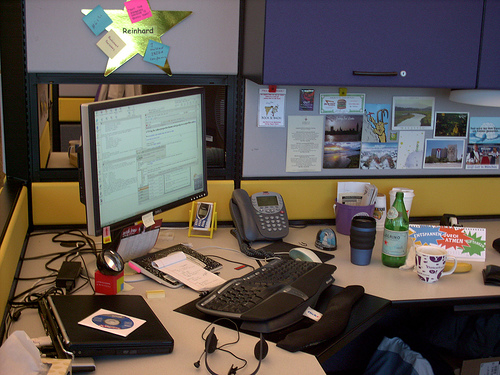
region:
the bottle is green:
[376, 181, 413, 270]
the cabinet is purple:
[266, 3, 491, 95]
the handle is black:
[347, 63, 401, 90]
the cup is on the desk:
[342, 209, 378, 268]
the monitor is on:
[81, 97, 210, 224]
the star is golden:
[64, 0, 209, 77]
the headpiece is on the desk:
[192, 316, 283, 373]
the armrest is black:
[279, 282, 366, 360]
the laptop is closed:
[31, 283, 180, 354]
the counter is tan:
[175, 322, 189, 366]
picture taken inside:
[9, 6, 493, 371]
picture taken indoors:
[26, 6, 478, 373]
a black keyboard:
[180, 251, 350, 341]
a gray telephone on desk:
[227, 185, 287, 240]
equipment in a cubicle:
[17, 105, 487, 367]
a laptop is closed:
[45, 295, 160, 361]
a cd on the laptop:
[77, 310, 142, 340]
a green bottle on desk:
[380, 185, 405, 270]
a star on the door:
[61, 6, 211, 71]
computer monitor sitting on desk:
[75, 85, 211, 242]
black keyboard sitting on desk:
[198, 251, 339, 326]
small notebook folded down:
[28, 285, 180, 367]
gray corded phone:
[226, 186, 294, 261]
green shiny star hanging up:
[80, 3, 198, 80]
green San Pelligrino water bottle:
[379, 185, 411, 274]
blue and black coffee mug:
[346, 212, 379, 265]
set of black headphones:
[189, 312, 280, 373]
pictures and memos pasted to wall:
[254, 85, 497, 180]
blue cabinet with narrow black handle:
[239, 0, 497, 94]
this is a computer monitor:
[71, 83, 204, 241]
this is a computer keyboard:
[192, 251, 344, 351]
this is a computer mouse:
[94, 233, 135, 286]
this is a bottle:
[382, 180, 413, 280]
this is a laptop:
[44, 280, 185, 370]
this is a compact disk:
[78, 306, 158, 346]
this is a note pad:
[142, 236, 219, 308]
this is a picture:
[184, 191, 218, 242]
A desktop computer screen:
[74, 87, 213, 239]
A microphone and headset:
[191, 321, 272, 373]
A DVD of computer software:
[73, 305, 147, 343]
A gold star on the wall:
[76, 4, 195, 82]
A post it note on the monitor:
[138, 212, 159, 229]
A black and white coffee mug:
[411, 244, 458, 288]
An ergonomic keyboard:
[193, 255, 337, 322]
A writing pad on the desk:
[151, 249, 227, 301]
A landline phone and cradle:
[225, 185, 294, 260]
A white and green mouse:
[281, 246, 331, 267]